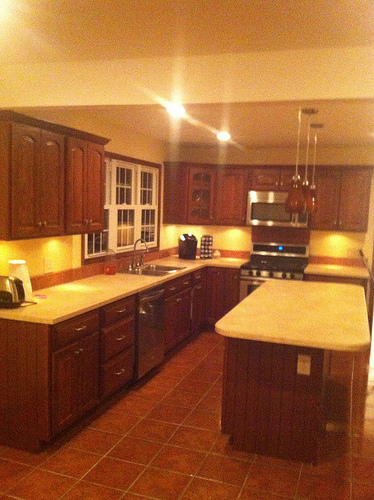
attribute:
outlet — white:
[41, 254, 54, 274]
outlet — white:
[295, 354, 311, 377]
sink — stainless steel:
[117, 262, 186, 279]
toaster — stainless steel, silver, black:
[1, 276, 26, 307]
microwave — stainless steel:
[243, 190, 309, 228]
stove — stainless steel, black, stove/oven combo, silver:
[239, 242, 309, 304]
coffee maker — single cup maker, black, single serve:
[178, 233, 199, 258]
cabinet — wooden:
[1, 111, 111, 242]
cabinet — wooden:
[165, 159, 215, 224]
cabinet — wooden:
[248, 162, 314, 193]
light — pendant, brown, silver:
[284, 107, 306, 214]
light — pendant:
[300, 122, 312, 212]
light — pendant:
[307, 133, 317, 214]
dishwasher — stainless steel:
[137, 287, 164, 383]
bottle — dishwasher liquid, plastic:
[102, 248, 119, 274]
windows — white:
[83, 157, 160, 255]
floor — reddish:
[0, 327, 373, 499]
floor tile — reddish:
[82, 454, 148, 492]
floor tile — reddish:
[148, 442, 208, 476]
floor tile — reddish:
[143, 402, 196, 426]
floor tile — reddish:
[239, 462, 301, 498]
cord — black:
[20, 301, 37, 310]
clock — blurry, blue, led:
[279, 246, 283, 249]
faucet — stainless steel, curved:
[130, 238, 149, 268]